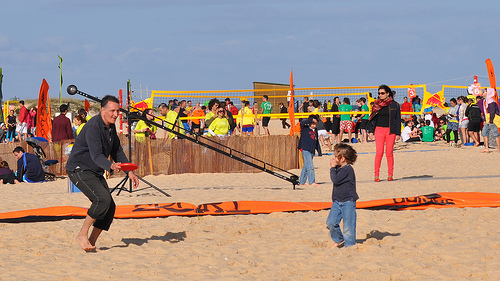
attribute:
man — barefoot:
[64, 98, 129, 233]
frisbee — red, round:
[119, 149, 141, 178]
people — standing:
[295, 92, 480, 124]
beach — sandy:
[414, 148, 459, 171]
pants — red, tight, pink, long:
[376, 129, 401, 180]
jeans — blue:
[297, 147, 336, 205]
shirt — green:
[419, 118, 438, 140]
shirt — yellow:
[234, 103, 253, 131]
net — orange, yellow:
[293, 97, 351, 105]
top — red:
[399, 94, 409, 116]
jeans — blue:
[332, 194, 370, 256]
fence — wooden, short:
[213, 130, 265, 189]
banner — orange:
[35, 78, 59, 135]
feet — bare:
[77, 229, 108, 262]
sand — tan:
[175, 236, 296, 276]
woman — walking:
[299, 110, 325, 193]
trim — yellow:
[413, 85, 424, 114]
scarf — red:
[363, 96, 391, 119]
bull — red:
[428, 92, 447, 115]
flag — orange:
[480, 53, 500, 107]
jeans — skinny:
[379, 136, 394, 169]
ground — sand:
[156, 232, 268, 235]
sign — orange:
[286, 69, 306, 129]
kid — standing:
[333, 142, 390, 255]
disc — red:
[99, 141, 142, 171]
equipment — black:
[168, 121, 313, 177]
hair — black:
[103, 95, 134, 100]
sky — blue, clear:
[68, 28, 331, 80]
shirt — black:
[66, 108, 122, 180]